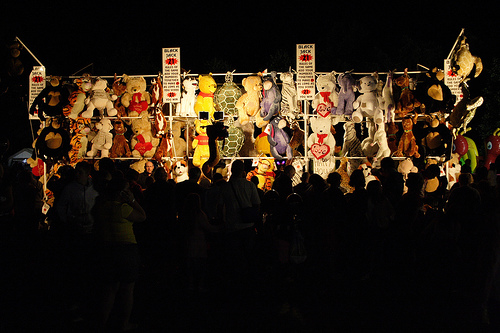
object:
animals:
[28, 73, 66, 116]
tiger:
[66, 76, 91, 115]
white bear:
[310, 71, 342, 116]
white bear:
[351, 71, 386, 121]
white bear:
[77, 75, 121, 119]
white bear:
[80, 115, 117, 159]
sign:
[294, 42, 317, 100]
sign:
[158, 44, 185, 105]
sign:
[26, 65, 49, 117]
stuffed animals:
[394, 113, 418, 159]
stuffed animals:
[167, 155, 191, 187]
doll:
[192, 73, 220, 121]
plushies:
[192, 116, 211, 172]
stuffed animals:
[418, 103, 446, 159]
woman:
[97, 155, 149, 312]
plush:
[88, 119, 111, 161]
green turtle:
[218, 121, 245, 158]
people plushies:
[10, 153, 492, 315]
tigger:
[65, 117, 89, 167]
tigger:
[245, 159, 273, 188]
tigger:
[39, 162, 62, 210]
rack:
[18, 68, 483, 79]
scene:
[7, 11, 492, 308]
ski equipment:
[237, 69, 265, 129]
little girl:
[173, 188, 221, 294]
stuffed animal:
[308, 71, 338, 116]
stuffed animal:
[256, 72, 280, 119]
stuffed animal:
[185, 118, 214, 168]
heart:
[309, 142, 330, 161]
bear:
[303, 111, 333, 163]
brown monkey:
[26, 112, 72, 166]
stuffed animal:
[196, 75, 216, 122]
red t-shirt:
[194, 135, 209, 146]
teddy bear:
[118, 76, 154, 119]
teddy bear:
[128, 118, 158, 158]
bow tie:
[319, 90, 331, 105]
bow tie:
[316, 132, 326, 146]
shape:
[29, 74, 68, 120]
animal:
[217, 74, 240, 125]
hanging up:
[210, 71, 238, 119]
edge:
[20, 74, 41, 166]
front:
[24, 158, 499, 303]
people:
[399, 172, 430, 269]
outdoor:
[26, 35, 488, 301]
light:
[129, 67, 335, 175]